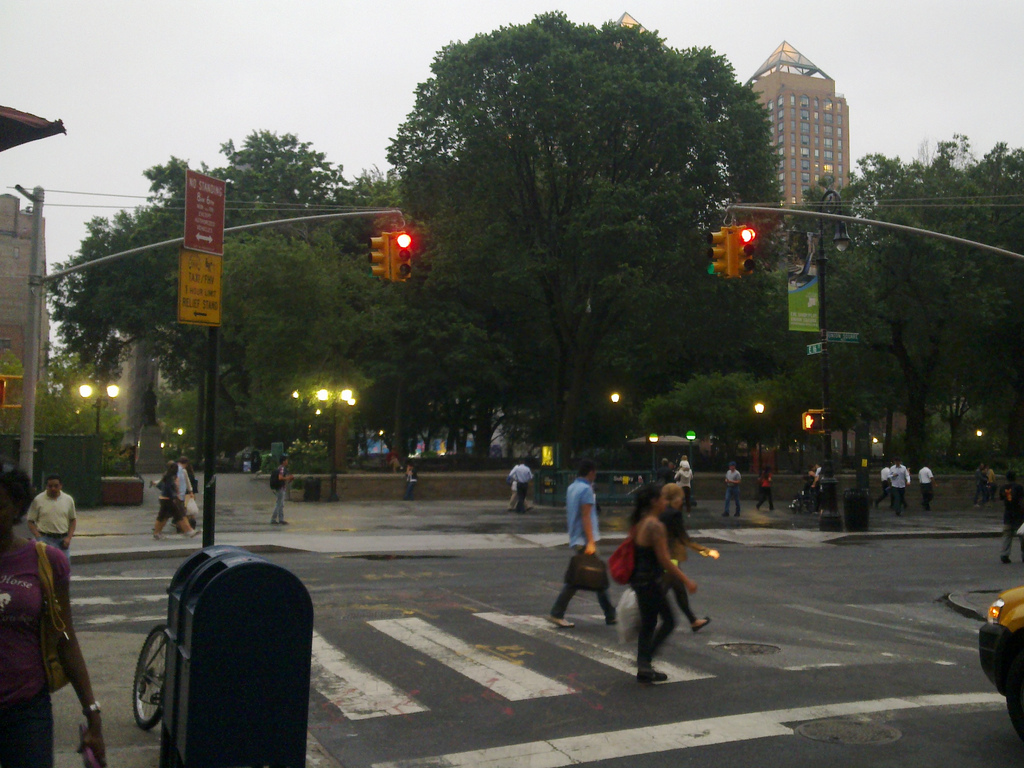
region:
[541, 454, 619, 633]
man in a light blue shirt walking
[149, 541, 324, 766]
two blue mail boxes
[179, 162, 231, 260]
a red parking sign with white letters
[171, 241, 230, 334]
a yellow parking sign with black letters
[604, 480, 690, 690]
a girl in a tank top with a red bag walking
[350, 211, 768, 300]
two red traffic lights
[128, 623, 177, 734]
the back wheel of a bicycle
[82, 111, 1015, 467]
a park with green bushy trees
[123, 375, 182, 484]
a statue of a person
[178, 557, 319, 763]
dark blue mailbox on street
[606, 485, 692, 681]
woman with pink bag crossing street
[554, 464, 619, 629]
man with blue shirt crossing street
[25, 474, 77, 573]
man wearing light yellow shirt crossing street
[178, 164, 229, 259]
red sign with white letters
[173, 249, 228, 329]
yellow sign with black letters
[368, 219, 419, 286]
traffic signal with red light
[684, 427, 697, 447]
green and white globe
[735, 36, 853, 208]
red building with triangle roof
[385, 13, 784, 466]
big, green tree between two traffic lights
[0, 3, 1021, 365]
cloud cover in sky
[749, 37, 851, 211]
top of city building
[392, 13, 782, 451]
green leaves of tree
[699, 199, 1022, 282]
traffic light on horizontal pole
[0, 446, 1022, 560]
people walking on sidewalk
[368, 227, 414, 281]
glowing red of traffic light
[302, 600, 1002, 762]
white painted blocks on aspalt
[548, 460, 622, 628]
walking man carrying bag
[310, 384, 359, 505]
glowing lights on top of pole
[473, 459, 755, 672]
People walking across the street.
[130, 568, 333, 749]
Two mailboxes on the corner of road.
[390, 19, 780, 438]
a tree with green leaves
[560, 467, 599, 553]
man wearing a blue shirt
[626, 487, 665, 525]
the woman has black hair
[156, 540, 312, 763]
blue postal boxes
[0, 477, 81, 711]
woman wearing a purple shirt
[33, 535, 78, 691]
brown handbag with shoulder strap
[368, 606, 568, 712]
white painted line on the road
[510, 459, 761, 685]
group of people crossing the street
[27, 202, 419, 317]
traffic light on a pole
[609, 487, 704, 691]
person crossing at crosswalk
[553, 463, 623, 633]
person crossing at crosswalk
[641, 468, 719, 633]
person crossing at crosswalk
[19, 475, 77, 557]
person crossing at crosswalk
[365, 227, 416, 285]
streetlight on pole is red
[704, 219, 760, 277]
streetlight on pole is red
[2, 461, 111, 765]
person walking on sidewalk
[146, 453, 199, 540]
person walking on sidewalk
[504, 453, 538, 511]
person walking on sidewalk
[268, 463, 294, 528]
person walking on sidewalk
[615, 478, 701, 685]
person walking in street wearing black pants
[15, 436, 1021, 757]
a bunch of people in street